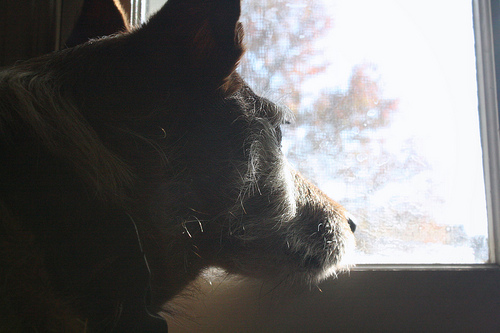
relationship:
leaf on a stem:
[319, 87, 380, 142] [324, 96, 412, 127]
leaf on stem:
[319, 87, 380, 142] [313, 69, 393, 138]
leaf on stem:
[290, 31, 305, 44] [256, 17, 313, 95]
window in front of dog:
[341, 70, 437, 180] [2, 1, 384, 330]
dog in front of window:
[2, 1, 384, 330] [341, 70, 437, 180]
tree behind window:
[235, 0, 394, 240] [253, 2, 498, 188]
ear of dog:
[132, 0, 249, 100] [2, 1, 384, 330]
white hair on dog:
[6, 60, 135, 205] [2, 1, 384, 330]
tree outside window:
[235, 0, 394, 240] [140, 0, 492, 257]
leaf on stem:
[296, 10, 314, 29] [286, 4, 305, 24]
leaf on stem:
[290, 31, 305, 44] [258, 25, 273, 50]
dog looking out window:
[2, 1, 384, 330] [140, 0, 492, 257]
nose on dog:
[347, 213, 357, 234] [2, 1, 384, 330]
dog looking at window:
[2, 1, 384, 330] [140, 0, 492, 257]